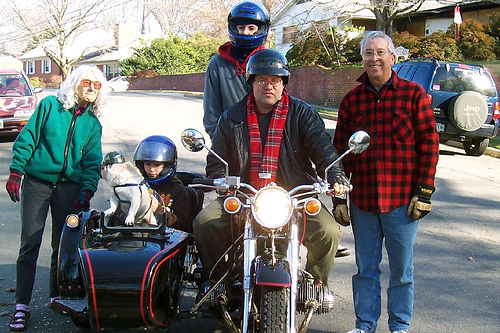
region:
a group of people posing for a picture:
[11, 10, 473, 313]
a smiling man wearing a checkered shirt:
[318, 23, 480, 328]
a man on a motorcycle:
[178, 44, 373, 312]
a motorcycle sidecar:
[59, 123, 222, 320]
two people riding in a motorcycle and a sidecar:
[48, 41, 363, 319]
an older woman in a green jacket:
[5, 59, 110, 322]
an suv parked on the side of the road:
[366, 45, 498, 173]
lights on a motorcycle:
[215, 169, 345, 233]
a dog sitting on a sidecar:
[79, 139, 167, 251]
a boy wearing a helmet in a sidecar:
[73, 141, 205, 313]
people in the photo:
[18, 17, 454, 231]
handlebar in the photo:
[169, 154, 259, 221]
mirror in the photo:
[328, 116, 380, 168]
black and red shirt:
[326, 77, 443, 202]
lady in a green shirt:
[27, 59, 129, 176]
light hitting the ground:
[113, 87, 181, 140]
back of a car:
[419, 49, 493, 147]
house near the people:
[267, 0, 362, 68]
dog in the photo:
[78, 138, 173, 228]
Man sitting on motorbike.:
[181, 44, 370, 330]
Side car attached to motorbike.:
[50, 132, 198, 327]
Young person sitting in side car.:
[131, 137, 197, 227]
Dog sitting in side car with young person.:
[98, 149, 159, 234]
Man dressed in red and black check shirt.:
[328, 68, 441, 217]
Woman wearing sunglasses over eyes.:
[76, 73, 107, 93]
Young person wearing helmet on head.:
[131, 130, 183, 185]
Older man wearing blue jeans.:
[348, 199, 427, 331]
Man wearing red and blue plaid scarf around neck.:
[237, 82, 298, 189]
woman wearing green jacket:
[11, 60, 134, 220]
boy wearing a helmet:
[120, 135, 170, 195]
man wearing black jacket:
[232, 45, 324, 175]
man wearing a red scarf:
[225, 40, 305, 195]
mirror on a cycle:
[331, 125, 371, 160]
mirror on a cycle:
[173, 120, 213, 165]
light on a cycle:
[245, 180, 297, 230]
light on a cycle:
[300, 185, 330, 210]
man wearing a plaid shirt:
[357, 20, 435, 304]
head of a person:
[242, 51, 287, 101]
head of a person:
[57, 48, 112, 120]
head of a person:
[132, 131, 192, 186]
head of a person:
[355, 21, 423, 89]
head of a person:
[225, 5, 267, 52]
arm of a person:
[68, 143, 110, 198]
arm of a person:
[184, 121, 271, 212]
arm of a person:
[311, 119, 358, 183]